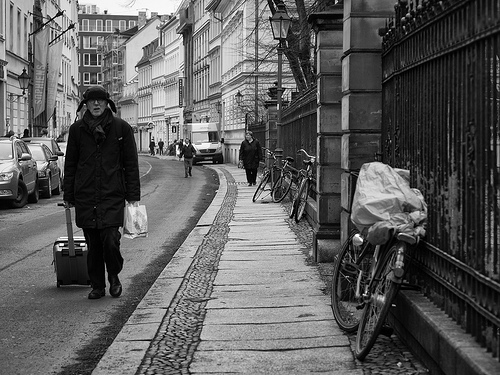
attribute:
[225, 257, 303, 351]
tiles — stone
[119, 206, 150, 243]
bag — white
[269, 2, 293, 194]
light — metal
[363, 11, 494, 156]
fence bars — black, metallic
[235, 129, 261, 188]
woman — walking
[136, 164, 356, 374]
sidewalk — stone